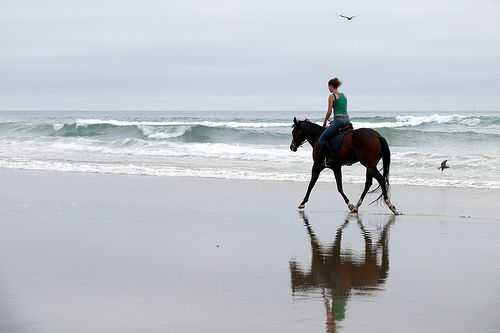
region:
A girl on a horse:
[296, 60, 383, 210]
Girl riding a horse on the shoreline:
[276, 66, 413, 266]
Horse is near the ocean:
[287, 112, 411, 222]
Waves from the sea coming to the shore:
[88, 95, 258, 194]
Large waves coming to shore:
[103, 97, 233, 194]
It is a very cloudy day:
[1, 37, 263, 105]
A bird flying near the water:
[428, 144, 470, 194]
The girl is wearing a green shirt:
[317, 84, 359, 124]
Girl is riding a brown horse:
[316, 91, 385, 195]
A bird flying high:
[325, 0, 365, 30]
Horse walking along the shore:
[277, 65, 422, 222]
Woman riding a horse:
[276, 68, 412, 220]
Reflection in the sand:
[279, 205, 414, 330]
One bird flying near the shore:
[423, 150, 465, 182]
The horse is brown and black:
[277, 67, 417, 220]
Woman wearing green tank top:
[281, 73, 404, 219]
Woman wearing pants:
[279, 68, 410, 217]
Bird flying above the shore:
[325, 5, 377, 41]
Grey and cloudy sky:
[5, 4, 487, 100]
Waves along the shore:
[1, 107, 498, 199]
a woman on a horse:
[268, 72, 418, 236]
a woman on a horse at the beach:
[260, 70, 422, 227]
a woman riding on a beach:
[269, 63, 447, 233]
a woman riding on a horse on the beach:
[271, 65, 440, 232]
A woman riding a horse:
[288, 67, 402, 237]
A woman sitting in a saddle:
[317, 75, 356, 165]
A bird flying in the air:
[334, 6, 366, 31]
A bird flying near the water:
[432, 153, 458, 180]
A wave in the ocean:
[55, 105, 267, 164]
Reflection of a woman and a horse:
[270, 202, 415, 332]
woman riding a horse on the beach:
[280, 76, 407, 214]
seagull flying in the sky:
[330, 3, 367, 28]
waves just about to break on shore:
[51, 108, 205, 152]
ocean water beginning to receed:
[17, 144, 489, 212]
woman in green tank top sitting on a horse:
[315, 74, 356, 153]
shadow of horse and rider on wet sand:
[285, 203, 401, 326]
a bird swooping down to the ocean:
[430, 150, 458, 176]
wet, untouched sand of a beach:
[31, 210, 448, 332]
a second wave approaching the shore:
[384, 109, 492, 154]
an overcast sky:
[35, 13, 279, 89]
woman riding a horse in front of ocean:
[281, 69, 413, 221]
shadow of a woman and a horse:
[266, 201, 407, 331]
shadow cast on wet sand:
[248, 195, 452, 325]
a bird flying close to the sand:
[414, 124, 492, 219]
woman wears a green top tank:
[305, 71, 358, 183]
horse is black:
[279, 115, 406, 216]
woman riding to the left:
[276, 62, 411, 229]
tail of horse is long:
[373, 127, 394, 205]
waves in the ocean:
[12, 101, 284, 173]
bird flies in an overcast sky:
[275, 2, 431, 55]